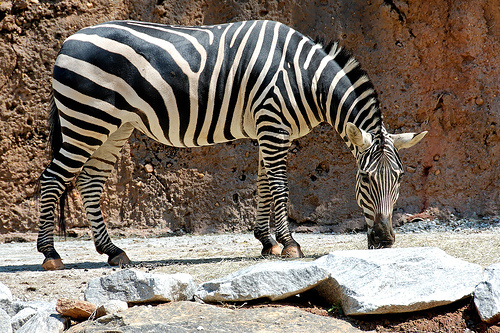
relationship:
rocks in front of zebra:
[312, 246, 476, 308] [60, 27, 399, 240]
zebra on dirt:
[60, 27, 399, 240] [154, 238, 220, 333]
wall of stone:
[384, 20, 467, 83] [380, 17, 495, 127]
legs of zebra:
[47, 152, 311, 257] [60, 27, 399, 240]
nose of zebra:
[368, 219, 398, 245] [60, 27, 399, 240]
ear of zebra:
[396, 126, 433, 150] [60, 27, 399, 240]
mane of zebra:
[329, 43, 392, 125] [60, 27, 399, 240]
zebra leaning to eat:
[60, 27, 399, 240] [361, 236, 435, 260]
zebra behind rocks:
[60, 27, 399, 240] [312, 246, 476, 308]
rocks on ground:
[312, 246, 476, 308] [0, 228, 496, 332]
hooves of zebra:
[262, 241, 308, 257] [60, 27, 399, 240]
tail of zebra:
[47, 104, 62, 150] [60, 27, 399, 240]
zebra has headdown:
[60, 27, 399, 240] [347, 132, 411, 241]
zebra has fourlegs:
[60, 27, 399, 240] [47, 152, 311, 257]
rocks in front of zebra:
[312, 246, 476, 308] [36, 18, 428, 271]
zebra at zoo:
[36, 18, 428, 271] [3, 4, 497, 333]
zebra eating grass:
[36, 18, 428, 271] [200, 248, 247, 272]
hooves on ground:
[262, 241, 308, 257] [0, 228, 496, 332]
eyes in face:
[358, 169, 372, 185] [347, 132, 411, 241]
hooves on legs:
[262, 241, 308, 257] [47, 152, 311, 257]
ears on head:
[396, 126, 433, 150] [347, 132, 411, 241]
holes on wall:
[396, 25, 427, 50] [384, 20, 467, 83]